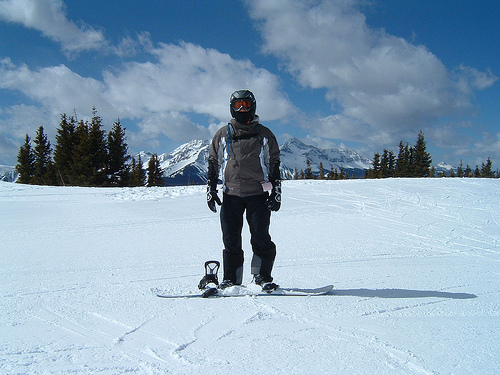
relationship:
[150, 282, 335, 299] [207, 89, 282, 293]
snowboard under man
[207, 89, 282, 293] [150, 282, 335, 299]
man wears snowboard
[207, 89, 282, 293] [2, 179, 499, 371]
man standing in snow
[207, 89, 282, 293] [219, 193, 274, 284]
man wearing ski pants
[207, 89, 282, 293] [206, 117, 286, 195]
man wearing ski jacket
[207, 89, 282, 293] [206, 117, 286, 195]
man wears ski jacket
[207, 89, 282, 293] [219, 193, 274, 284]
man wears ski pants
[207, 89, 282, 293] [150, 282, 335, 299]
man on snowboard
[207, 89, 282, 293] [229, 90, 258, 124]
man wearing helmet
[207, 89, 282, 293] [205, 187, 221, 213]
man wearing glove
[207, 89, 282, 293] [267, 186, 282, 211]
man wearing glove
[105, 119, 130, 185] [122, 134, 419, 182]
tree in front of mountain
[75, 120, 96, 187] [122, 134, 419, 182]
tree in front of mountain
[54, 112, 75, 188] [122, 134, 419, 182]
tree in front of mountain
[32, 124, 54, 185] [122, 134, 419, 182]
tree in front of mountain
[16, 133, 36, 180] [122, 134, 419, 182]
tree in front of mountain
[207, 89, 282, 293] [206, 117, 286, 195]
man has ski jacket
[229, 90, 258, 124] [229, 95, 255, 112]
helmet has goggles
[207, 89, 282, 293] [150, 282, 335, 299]
man standing on snowboard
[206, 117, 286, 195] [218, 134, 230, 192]
ski jacket has side stripe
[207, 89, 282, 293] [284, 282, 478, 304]
man has shadow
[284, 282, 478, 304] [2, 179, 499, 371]
shadow on top of snow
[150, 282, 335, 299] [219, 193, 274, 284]
snowboard wearing ski pants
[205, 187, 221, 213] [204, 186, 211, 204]
glove has design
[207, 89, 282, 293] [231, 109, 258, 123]
man wears mask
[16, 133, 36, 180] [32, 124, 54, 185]
tree next to tree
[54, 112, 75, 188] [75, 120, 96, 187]
tree next to tree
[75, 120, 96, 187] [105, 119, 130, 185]
tree next to tree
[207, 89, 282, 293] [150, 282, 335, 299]
man posing on snowboard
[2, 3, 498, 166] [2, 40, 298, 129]
sky has cloud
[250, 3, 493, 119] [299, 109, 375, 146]
cloud flying next to cloud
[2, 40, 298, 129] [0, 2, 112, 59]
cloud flying next to cloud